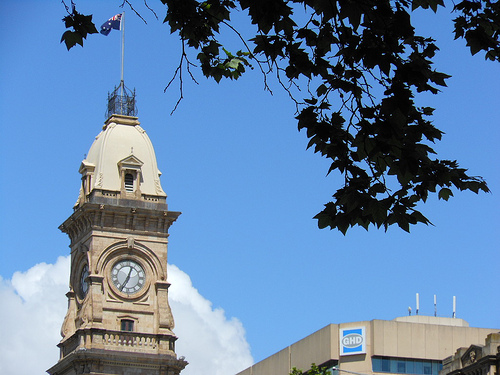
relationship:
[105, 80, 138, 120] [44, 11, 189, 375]
decoration above building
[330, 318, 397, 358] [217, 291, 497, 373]
sign on building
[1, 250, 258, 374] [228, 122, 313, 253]
cloud in sky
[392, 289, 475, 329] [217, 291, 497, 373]
radio antanas on building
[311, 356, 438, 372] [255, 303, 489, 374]
panes on building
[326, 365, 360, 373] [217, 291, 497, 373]
street light near building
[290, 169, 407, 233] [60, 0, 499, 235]
leaves on branches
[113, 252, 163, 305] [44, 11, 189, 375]
clock on building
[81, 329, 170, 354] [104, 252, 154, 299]
balcony on clock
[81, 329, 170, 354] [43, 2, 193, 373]
balcony on tower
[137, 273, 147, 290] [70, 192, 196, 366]
roman numerals on clock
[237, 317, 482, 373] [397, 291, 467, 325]
building with antenna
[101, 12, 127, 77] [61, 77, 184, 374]
flag on clock tower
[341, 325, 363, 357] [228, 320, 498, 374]
sign on building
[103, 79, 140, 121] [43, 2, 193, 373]
decoration on top of tower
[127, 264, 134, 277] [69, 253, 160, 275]
hand on clock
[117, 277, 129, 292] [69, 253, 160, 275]
hand on clock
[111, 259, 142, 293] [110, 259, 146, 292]
numerals on clock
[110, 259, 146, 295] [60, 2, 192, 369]
clock on tower